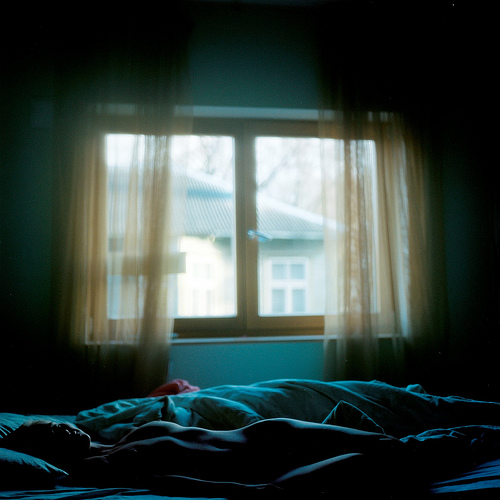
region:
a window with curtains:
[12, 36, 494, 418]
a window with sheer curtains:
[44, 71, 495, 383]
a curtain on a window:
[89, 81, 499, 378]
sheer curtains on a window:
[29, 65, 498, 402]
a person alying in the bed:
[55, 336, 431, 498]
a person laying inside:
[42, 356, 454, 491]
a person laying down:
[83, 350, 425, 495]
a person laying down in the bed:
[92, 379, 389, 499]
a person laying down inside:
[62, 358, 434, 498]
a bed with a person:
[158, 366, 428, 488]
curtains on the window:
[64, 96, 429, 411]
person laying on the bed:
[5, 398, 497, 496]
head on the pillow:
[1, 408, 105, 498]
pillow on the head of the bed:
[0, 403, 96, 498]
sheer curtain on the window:
[72, 91, 184, 401]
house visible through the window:
[108, 132, 340, 317]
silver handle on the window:
[244, 227, 280, 246]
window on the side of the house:
[258, 254, 321, 316]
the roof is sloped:
[91, 151, 337, 251]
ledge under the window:
[86, 322, 417, 357]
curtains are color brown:
[40, 65, 460, 385]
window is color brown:
[85, 107, 405, 340]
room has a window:
[6, 40, 493, 403]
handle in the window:
[239, 221, 276, 250]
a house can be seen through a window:
[95, 158, 351, 312]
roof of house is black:
[101, 159, 334, 247]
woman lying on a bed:
[7, 372, 495, 498]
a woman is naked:
[1, 402, 478, 498]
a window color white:
[260, 246, 317, 316]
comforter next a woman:
[1, 364, 498, 494]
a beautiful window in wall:
[66, 125, 423, 330]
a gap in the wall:
[231, 136, 282, 323]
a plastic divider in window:
[225, 139, 273, 328]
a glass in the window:
[263, 150, 366, 301]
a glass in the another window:
[114, 146, 244, 308]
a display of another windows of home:
[261, 243, 311, 318]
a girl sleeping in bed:
[19, 386, 376, 494]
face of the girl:
[20, 410, 104, 465]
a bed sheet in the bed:
[191, 361, 338, 408]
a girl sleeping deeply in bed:
[31, 399, 452, 488]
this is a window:
[72, 94, 414, 344]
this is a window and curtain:
[57, 20, 452, 396]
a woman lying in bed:
[6, 410, 478, 497]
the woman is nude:
[15, 390, 496, 490]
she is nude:
[7, 401, 487, 496]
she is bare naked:
[5, 390, 463, 496]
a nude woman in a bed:
[5, 397, 495, 497]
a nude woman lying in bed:
[7, 391, 478, 496]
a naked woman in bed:
[0, 395, 490, 495]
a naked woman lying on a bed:
[0, 396, 463, 496]